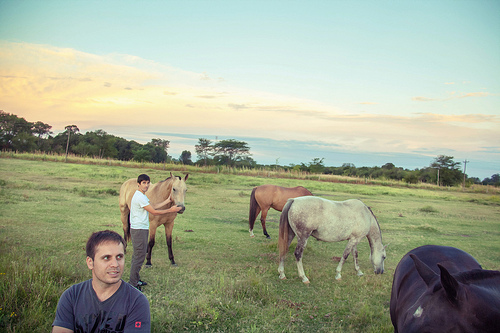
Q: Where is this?
A: This is at the field.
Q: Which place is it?
A: It is a field.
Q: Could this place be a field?
A: Yes, it is a field.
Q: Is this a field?
A: Yes, it is a field.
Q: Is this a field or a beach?
A: It is a field.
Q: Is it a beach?
A: No, it is a field.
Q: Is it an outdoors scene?
A: Yes, it is outdoors.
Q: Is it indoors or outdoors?
A: It is outdoors.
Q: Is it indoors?
A: No, it is outdoors.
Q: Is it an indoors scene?
A: No, it is outdoors.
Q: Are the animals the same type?
A: Yes, all the animals are horses.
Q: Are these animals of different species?
A: No, all the animals are horses.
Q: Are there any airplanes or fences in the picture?
A: No, there are no fences or airplanes.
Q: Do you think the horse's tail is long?
A: Yes, the tail is long.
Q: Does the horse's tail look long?
A: Yes, the tail is long.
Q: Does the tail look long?
A: Yes, the tail is long.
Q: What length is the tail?
A: The tail is long.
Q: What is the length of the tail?
A: The tail is long.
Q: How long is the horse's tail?
A: The tail is long.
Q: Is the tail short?
A: No, the tail is long.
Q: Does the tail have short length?
A: No, the tail is long.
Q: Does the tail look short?
A: No, the tail is long.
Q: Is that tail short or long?
A: The tail is long.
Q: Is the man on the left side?
A: Yes, the man is on the left of the image.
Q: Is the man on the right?
A: No, the man is on the left of the image.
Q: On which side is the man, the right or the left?
A: The man is on the left of the image.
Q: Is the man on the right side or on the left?
A: The man is on the left of the image.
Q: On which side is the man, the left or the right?
A: The man is on the left of the image.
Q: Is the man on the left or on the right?
A: The man is on the left of the image.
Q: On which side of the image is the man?
A: The man is on the left of the image.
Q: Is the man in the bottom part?
A: Yes, the man is in the bottom of the image.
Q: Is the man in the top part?
A: No, the man is in the bottom of the image.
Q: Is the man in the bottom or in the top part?
A: The man is in the bottom of the image.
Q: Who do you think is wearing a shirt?
A: The man is wearing a shirt.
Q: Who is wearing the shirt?
A: The man is wearing a shirt.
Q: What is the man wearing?
A: The man is wearing a shirt.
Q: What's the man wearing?
A: The man is wearing a shirt.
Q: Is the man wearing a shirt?
A: Yes, the man is wearing a shirt.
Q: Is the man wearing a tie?
A: No, the man is wearing a shirt.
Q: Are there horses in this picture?
A: Yes, there is a horse.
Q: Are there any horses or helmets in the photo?
A: Yes, there is a horse.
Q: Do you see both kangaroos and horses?
A: No, there is a horse but no kangaroos.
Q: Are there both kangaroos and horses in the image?
A: No, there is a horse but no kangaroos.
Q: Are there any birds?
A: No, there are no birds.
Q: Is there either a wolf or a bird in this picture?
A: No, there are no birds or wolves.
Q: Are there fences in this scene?
A: No, there are no fences.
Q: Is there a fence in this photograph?
A: No, there are no fences.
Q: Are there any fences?
A: No, there are no fences.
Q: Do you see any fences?
A: No, there are no fences.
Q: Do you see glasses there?
A: No, there are no glasses.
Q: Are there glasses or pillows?
A: No, there are no glasses or pillows.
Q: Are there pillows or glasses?
A: No, there are no glasses or pillows.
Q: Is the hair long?
A: Yes, the hair is long.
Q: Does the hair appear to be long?
A: Yes, the hair is long.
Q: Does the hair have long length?
A: Yes, the hair is long.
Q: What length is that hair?
A: The hair is long.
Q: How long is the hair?
A: The hair is long.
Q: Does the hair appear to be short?
A: No, the hair is long.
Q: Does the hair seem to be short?
A: No, the hair is long.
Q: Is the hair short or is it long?
A: The hair is long.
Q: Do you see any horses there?
A: Yes, there is a horse.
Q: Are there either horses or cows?
A: Yes, there is a horse.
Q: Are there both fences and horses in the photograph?
A: No, there is a horse but no fences.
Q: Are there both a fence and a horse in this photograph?
A: No, there is a horse but no fences.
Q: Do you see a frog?
A: No, there are no frogs.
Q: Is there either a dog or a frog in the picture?
A: No, there are no frogs or dogs.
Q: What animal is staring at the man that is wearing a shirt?
A: The horse is staring at the man.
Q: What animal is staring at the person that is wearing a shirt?
A: The horse is staring at the man.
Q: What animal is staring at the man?
A: The horse is staring at the man.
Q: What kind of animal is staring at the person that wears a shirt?
A: The animal is a horse.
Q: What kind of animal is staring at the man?
A: The animal is a horse.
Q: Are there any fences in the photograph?
A: No, there are no fences.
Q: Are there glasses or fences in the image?
A: No, there are no fences or glasses.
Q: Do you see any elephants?
A: No, there are no elephants.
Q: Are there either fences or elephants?
A: No, there are no elephants or fences.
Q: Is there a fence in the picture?
A: No, there are no fences.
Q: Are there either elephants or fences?
A: No, there are no fences or elephants.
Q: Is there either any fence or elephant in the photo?
A: No, there are no fences or elephants.